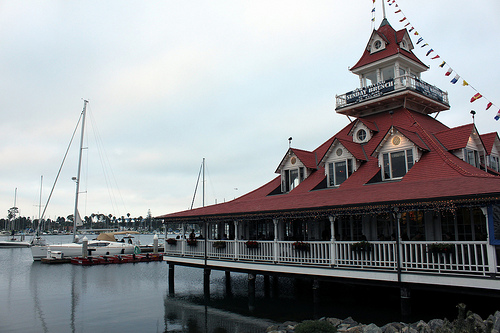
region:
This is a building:
[236, 47, 497, 259]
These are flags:
[454, 57, 473, 102]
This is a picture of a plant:
[413, 225, 473, 275]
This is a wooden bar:
[266, 209, 290, 244]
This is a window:
[316, 160, 369, 185]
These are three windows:
[183, 130, 415, 220]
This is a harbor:
[35, 230, 143, 315]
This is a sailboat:
[53, 200, 180, 293]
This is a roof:
[200, 193, 325, 266]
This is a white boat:
[49, 161, 171, 279]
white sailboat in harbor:
[38, 97, 177, 272]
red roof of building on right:
[222, 110, 487, 208]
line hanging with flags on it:
[383, 7, 492, 116]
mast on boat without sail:
[68, 113, 120, 228]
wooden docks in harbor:
[79, 241, 199, 290]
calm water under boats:
[18, 228, 170, 326]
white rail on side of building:
[196, 233, 487, 303]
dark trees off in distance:
[23, 208, 167, 228]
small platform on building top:
[335, 79, 458, 111]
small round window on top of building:
[368, 38, 383, 55]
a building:
[156, 10, 498, 312]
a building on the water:
[153, 10, 498, 304]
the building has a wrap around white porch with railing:
[157, 202, 497, 295]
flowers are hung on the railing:
[152, 228, 494, 271]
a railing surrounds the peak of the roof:
[333, 9, 461, 126]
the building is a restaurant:
[158, 9, 498, 316]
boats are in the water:
[9, 86, 214, 279]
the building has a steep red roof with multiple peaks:
[172, 13, 499, 287]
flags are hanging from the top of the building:
[367, 0, 499, 139]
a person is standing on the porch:
[179, 223, 212, 242]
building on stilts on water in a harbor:
[155, 8, 498, 306]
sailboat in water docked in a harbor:
[26, 93, 147, 267]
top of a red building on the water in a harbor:
[327, 13, 452, 118]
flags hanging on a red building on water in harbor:
[387, 0, 499, 121]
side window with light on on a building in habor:
[362, 120, 434, 186]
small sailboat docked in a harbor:
[0, 182, 32, 251]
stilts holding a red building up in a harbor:
[156, 261, 223, 303]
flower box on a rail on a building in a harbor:
[287, 238, 317, 254]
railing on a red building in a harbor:
[158, 231, 498, 291]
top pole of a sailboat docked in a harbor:
[67, 97, 93, 233]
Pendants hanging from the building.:
[390, 5, 485, 100]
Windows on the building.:
[263, 145, 426, 191]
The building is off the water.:
[143, 194, 408, 299]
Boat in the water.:
[28, 228, 158, 266]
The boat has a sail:
[68, 110, 81, 227]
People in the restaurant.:
[187, 220, 230, 247]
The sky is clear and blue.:
[93, 45, 335, 147]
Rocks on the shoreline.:
[307, 312, 467, 331]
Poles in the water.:
[162, 258, 229, 305]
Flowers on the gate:
[331, 237, 382, 255]